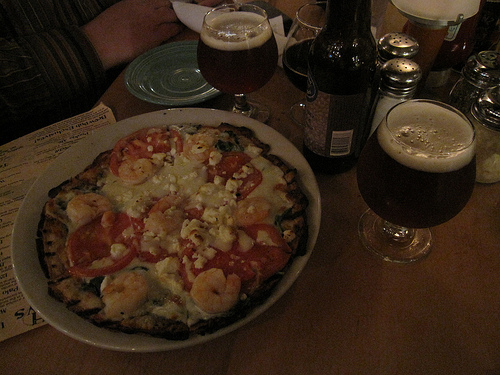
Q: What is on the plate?
A: Pizza.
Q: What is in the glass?
A: Dark beer.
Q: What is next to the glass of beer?
A: A bottle of beer.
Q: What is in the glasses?
A: Beer.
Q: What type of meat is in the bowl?
A: Shrimp.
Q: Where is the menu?
A: On the table beneath the bowl.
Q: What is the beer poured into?
A: Two clear glasses.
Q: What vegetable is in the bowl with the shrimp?
A: Tomatoes.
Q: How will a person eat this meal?
A: With the utensils rolled in the napkin on the table.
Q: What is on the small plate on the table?
A: Nothing, it is clean.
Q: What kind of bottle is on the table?
A: A beer bottle.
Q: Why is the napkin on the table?
A: To clean up after the meal.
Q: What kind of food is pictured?
A: Pizza.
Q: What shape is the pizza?
A: Round.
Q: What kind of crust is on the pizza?
A: Thin crust.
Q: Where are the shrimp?
A: On the pizza.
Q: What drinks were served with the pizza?
A: Beer.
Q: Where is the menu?
A: Under the pizza plate.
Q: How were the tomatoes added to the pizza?
A: In slices.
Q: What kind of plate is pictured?
A: A ceramic plate.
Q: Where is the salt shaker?
A: Next to the beer bottle.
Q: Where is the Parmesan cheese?
A: In a glass shaker.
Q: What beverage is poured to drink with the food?
A: Beer.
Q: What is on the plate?
A: Seafood pizza.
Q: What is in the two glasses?
A: Beer.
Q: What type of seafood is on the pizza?
A: Shrimp.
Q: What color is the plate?
A: White.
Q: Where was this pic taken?
A: Restaurant.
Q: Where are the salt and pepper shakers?
A: Behind the beer bottle.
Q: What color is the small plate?
A: Green.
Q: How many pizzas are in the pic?
A: 1.